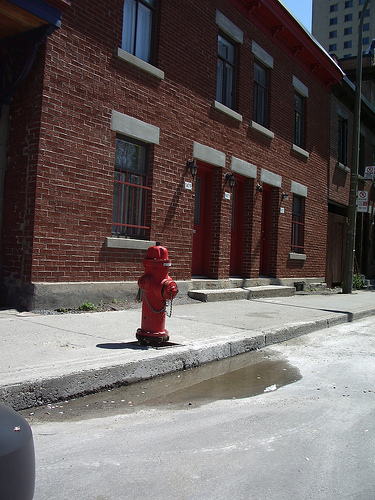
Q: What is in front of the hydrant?
A: Puddle.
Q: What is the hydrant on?
A: Sidewalk.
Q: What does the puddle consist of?
A: Water.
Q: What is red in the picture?
A: A hydrant.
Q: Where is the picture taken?
A: A building.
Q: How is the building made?
A: Of brick.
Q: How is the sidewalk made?
A: Of concrete.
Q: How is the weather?
A: Sunny.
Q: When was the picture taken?
A: Afternoon.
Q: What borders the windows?
A: Stone.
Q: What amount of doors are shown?
A: 3.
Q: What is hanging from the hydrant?
A: Chains.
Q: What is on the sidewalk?
A: Hydrant.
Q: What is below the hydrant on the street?
A: Water.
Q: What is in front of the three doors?
A: Concrete steps.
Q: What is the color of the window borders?
A: Grey.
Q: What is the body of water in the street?
A: A puddle.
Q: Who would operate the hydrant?
A: A fireman.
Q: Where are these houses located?
A: In the city.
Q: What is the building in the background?
A: A highrise.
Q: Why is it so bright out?
A: It's daytime.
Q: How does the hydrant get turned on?
A: With a wrench.